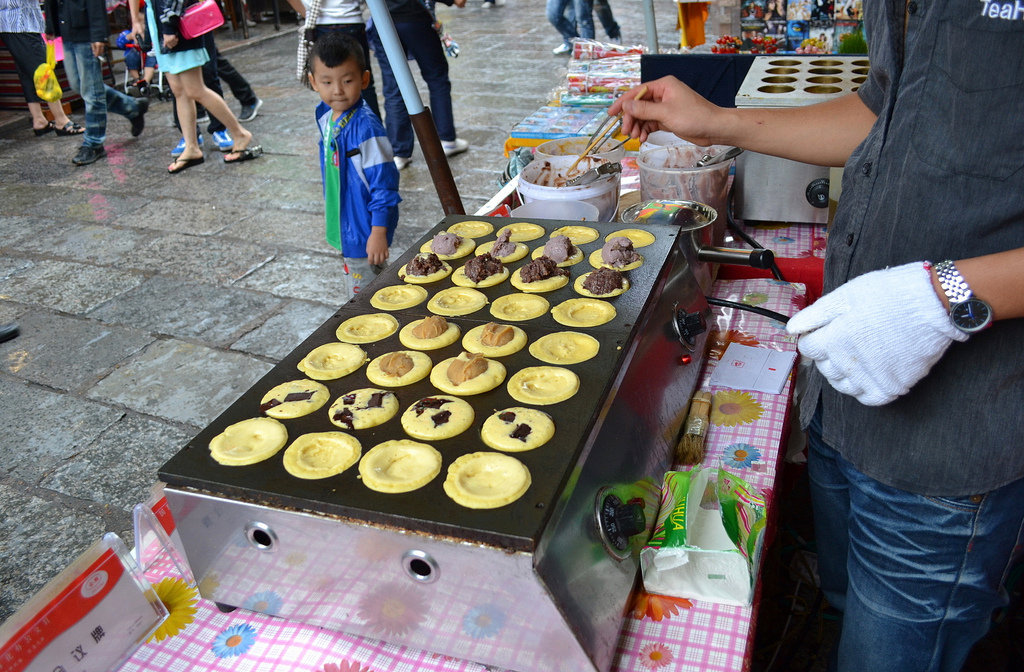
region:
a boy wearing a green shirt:
[297, 31, 411, 269]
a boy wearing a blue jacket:
[300, 31, 405, 276]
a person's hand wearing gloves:
[788, 239, 1020, 405]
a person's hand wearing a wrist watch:
[849, 238, 1017, 341]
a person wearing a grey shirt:
[782, 1, 1018, 517]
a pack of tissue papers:
[643, 466, 764, 609]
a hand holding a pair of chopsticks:
[580, 65, 737, 183]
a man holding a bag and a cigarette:
[28, 12, 127, 169]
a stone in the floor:
[65, 158, 132, 204]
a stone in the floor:
[157, 158, 240, 200]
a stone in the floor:
[246, 162, 338, 208]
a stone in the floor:
[98, 230, 277, 288]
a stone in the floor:
[22, 203, 163, 270]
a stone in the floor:
[3, 304, 150, 390]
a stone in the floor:
[88, 323, 279, 432]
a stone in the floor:
[21, 379, 192, 507]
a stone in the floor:
[5, 476, 110, 628]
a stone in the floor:
[466, 94, 542, 152]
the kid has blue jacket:
[287, 17, 420, 287]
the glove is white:
[773, 240, 971, 419]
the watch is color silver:
[926, 243, 1002, 357]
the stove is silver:
[125, 200, 752, 669]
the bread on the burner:
[442, 445, 537, 522]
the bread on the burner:
[363, 423, 444, 500]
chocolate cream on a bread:
[427, 341, 514, 402]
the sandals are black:
[160, 131, 275, 182]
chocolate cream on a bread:
[512, 248, 570, 300]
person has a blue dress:
[129, 2, 270, 179]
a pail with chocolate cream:
[506, 134, 628, 227]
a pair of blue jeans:
[56, 37, 146, 142]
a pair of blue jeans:
[367, 11, 462, 155]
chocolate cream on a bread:
[458, 314, 532, 363]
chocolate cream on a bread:
[364, 342, 413, 380]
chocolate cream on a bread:
[422, 345, 508, 399]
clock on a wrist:
[928, 252, 1005, 341]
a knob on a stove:
[579, 466, 660, 574]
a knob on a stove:
[651, 284, 732, 362]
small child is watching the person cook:
[273, 31, 425, 275]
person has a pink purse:
[164, 6, 238, 54]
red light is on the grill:
[672, 341, 699, 373]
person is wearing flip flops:
[163, 135, 272, 181]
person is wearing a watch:
[916, 246, 994, 349]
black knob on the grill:
[590, 474, 655, 566]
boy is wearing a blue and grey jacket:
[292, 40, 410, 275]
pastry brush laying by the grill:
[678, 375, 724, 474]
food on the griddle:
[456, 443, 494, 507]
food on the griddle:
[275, 423, 315, 493]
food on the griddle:
[198, 414, 241, 478]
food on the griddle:
[500, 408, 552, 478]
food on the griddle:
[409, 373, 458, 440]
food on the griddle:
[342, 358, 377, 416]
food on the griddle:
[242, 355, 323, 436]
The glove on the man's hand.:
[793, 256, 974, 412]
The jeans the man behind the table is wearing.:
[798, 439, 1018, 668]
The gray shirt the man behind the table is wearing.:
[785, 5, 1019, 492]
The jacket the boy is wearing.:
[315, 97, 395, 265]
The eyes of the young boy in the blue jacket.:
[321, 72, 360, 89]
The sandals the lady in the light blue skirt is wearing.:
[167, 145, 263, 172]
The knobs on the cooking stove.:
[606, 274, 709, 566]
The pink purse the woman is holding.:
[172, 9, 227, 44]